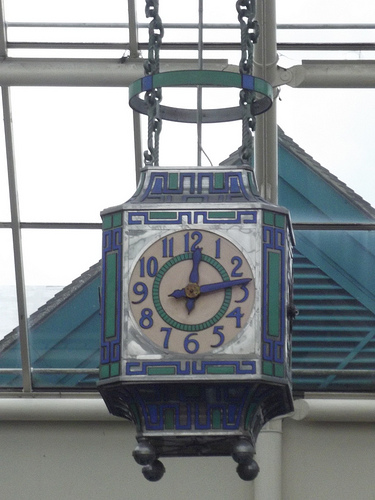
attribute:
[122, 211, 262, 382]
clock face — gray, blue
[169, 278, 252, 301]
clock arm — black, blue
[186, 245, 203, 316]
clock arm — black, blue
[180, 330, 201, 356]
number six — small, blue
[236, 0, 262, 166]
chain — matching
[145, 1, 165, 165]
chain — matching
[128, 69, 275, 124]
ring support — gray, striped, blue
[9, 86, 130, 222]
glass window piece — small, square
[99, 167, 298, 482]
aztec design — blue, gray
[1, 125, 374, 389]
roof — peaked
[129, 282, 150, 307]
number nine — curly, blue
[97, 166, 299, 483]
clock — green, large, blue, hanging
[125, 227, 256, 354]
time — 12:13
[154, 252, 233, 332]
circle — green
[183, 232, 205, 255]
arabic number — the number, blue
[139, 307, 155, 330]
arabic number — blue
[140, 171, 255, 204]
decoration — blue, green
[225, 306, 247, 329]
number 4 — blue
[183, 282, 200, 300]
flower — gold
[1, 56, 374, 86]
metal beam — gray